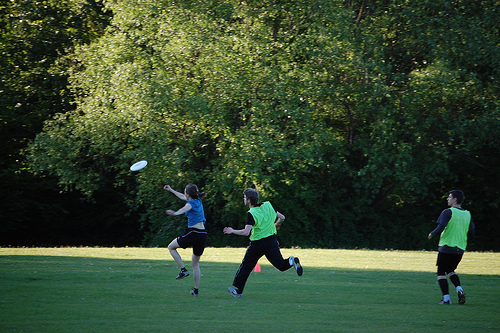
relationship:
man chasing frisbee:
[164, 169, 204, 290] [108, 133, 158, 175]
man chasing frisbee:
[163, 182, 212, 298] [109, 134, 151, 192]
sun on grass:
[44, 195, 475, 295] [24, 180, 457, 321]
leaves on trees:
[160, 32, 268, 110] [38, 14, 359, 246]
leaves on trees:
[274, 52, 457, 234] [115, 24, 369, 183]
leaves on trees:
[257, 63, 287, 116] [107, 55, 400, 216]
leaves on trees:
[364, 51, 402, 141] [55, 19, 406, 187]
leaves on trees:
[244, 60, 311, 167] [91, 18, 386, 202]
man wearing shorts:
[163, 182, 212, 298] [154, 199, 245, 267]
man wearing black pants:
[222, 186, 303, 299] [231, 235, 294, 294]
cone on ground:
[251, 249, 277, 288] [10, 191, 484, 321]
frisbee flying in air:
[130, 160, 148, 171] [67, 22, 89, 68]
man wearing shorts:
[163, 182, 212, 298] [164, 211, 218, 321]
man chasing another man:
[163, 182, 212, 298] [240, 187, 285, 294]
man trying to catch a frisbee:
[163, 182, 212, 298] [124, 151, 172, 195]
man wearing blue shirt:
[163, 182, 212, 298] [157, 172, 220, 321]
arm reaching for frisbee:
[162, 184, 184, 203] [130, 160, 148, 171]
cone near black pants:
[253, 260, 260, 272] [231, 235, 287, 283]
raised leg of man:
[169, 234, 186, 266] [163, 182, 212, 298]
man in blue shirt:
[163, 182, 212, 298] [186, 199, 206, 226]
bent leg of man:
[262, 246, 291, 269] [222, 186, 304, 296]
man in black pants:
[222, 186, 304, 296] [231, 235, 294, 294]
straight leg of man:
[233, 240, 260, 290] [222, 186, 304, 296]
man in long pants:
[222, 186, 304, 296] [230, 235, 290, 290]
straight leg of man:
[190, 246, 203, 285] [163, 182, 212, 298]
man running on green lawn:
[222, 186, 304, 296] [305, 251, 431, 327]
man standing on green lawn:
[426, 186, 472, 303] [305, 251, 431, 327]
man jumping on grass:
[163, 182, 212, 298] [0, 242, 494, 333]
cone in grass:
[253, 260, 260, 272] [255, 276, 401, 330]